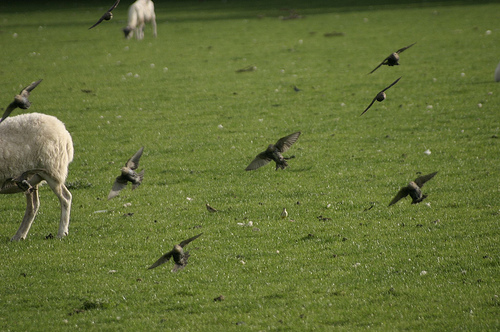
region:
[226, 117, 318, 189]
gray bird in the middle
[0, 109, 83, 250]
backside of white animal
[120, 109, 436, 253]
birds flying close to ground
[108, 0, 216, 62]
white animal in the background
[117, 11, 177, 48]
animal eating the grass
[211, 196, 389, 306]
items on the ground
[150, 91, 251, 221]
grass is green in spots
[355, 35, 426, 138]
two birds flying parallel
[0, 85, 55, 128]
bird near white animal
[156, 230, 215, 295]
bird close to the ground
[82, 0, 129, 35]
The bird is airborne.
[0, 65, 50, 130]
The bird is airborne.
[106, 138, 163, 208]
The bird is airborne.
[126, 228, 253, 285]
The bird is airborne.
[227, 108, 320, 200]
The bird is airborne.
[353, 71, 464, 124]
The bird is airborne.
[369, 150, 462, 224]
The bird is airborne.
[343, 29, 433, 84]
The bird is airborne.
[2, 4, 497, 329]
The grass is green.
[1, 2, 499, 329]
The grass is short.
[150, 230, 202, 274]
a small black bird in flight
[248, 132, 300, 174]
a small black bird in flight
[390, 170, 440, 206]
a small black bird in flight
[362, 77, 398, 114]
a small black bird in flight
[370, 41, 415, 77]
a small black bird in flight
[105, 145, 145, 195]
a small black bird in flight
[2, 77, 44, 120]
a small black bird in flight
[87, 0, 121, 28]
a small black bird in flight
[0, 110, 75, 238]
a white sheep standing in field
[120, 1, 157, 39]
a white sheep grazing in field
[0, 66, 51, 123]
The bird is flying.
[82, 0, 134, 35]
The bird is flying.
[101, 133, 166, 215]
The bird is flying.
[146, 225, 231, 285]
The bird is flying.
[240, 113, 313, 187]
The bird is flying.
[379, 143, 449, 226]
The bird is flying.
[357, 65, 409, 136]
The bird is flying.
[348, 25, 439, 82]
The bird is flying.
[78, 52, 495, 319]
birds flying in a group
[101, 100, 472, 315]
small birds that are flying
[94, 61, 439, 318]
black birds that are flying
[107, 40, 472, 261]
birds flying over the ground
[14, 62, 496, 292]
small birds flying over the ground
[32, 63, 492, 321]
birds flying over teh grass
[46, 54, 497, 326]
small birds flying over the grass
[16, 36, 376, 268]
sheep in a field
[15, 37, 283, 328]
sheep on the grass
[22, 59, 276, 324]
sheep standing outside